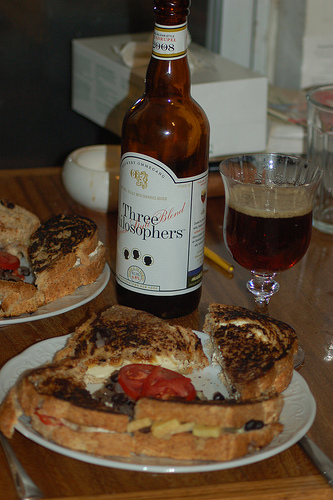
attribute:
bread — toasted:
[207, 301, 307, 401]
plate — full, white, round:
[0, 324, 317, 477]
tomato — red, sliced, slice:
[114, 359, 191, 401]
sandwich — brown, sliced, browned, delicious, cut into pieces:
[21, 293, 300, 470]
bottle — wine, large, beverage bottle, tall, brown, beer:
[109, 4, 212, 314]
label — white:
[113, 147, 206, 297]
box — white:
[69, 31, 282, 160]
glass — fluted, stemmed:
[217, 152, 321, 331]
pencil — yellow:
[203, 239, 235, 281]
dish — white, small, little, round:
[62, 143, 127, 213]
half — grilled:
[28, 360, 284, 459]